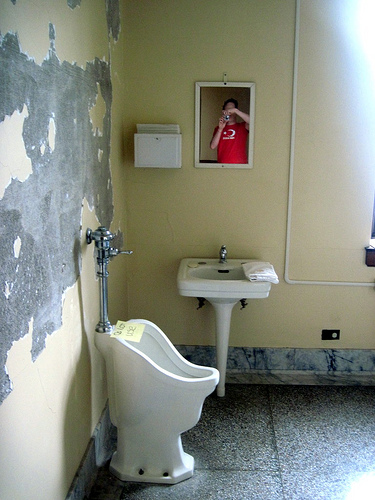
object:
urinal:
[95, 317, 219, 485]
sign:
[110, 321, 146, 343]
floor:
[86, 382, 374, 500]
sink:
[176, 256, 272, 300]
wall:
[125, 0, 374, 349]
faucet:
[219, 244, 229, 260]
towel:
[241, 261, 279, 283]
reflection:
[211, 98, 249, 162]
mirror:
[200, 88, 249, 163]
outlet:
[321, 330, 340, 340]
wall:
[0, 0, 126, 499]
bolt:
[162, 471, 170, 477]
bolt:
[139, 469, 145, 474]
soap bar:
[187, 260, 199, 268]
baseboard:
[271, 344, 373, 386]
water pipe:
[282, 0, 374, 287]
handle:
[120, 249, 133, 255]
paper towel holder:
[132, 122, 184, 169]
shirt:
[213, 123, 249, 163]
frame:
[194, 81, 254, 169]